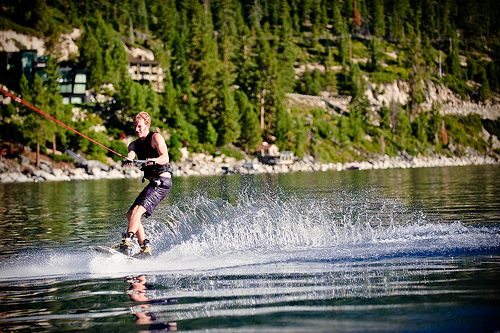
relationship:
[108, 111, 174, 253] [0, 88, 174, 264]
man enjoying skiing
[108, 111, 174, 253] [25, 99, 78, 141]
man being pulled rope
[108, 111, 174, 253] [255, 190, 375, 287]
man moving through water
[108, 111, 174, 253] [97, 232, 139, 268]
man on ski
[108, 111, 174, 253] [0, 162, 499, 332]
man water skiing on body/water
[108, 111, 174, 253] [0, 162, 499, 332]
man skiing on body/water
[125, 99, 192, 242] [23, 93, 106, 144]
man holding line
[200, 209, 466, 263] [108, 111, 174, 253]
wake behind a man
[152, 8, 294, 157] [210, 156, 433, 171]
trees along shore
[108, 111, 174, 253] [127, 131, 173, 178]
man wearing a clothes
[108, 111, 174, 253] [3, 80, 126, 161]
man holding onto rope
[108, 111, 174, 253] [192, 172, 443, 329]
man skiing on water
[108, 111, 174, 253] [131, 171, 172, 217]
man wearing swim trunks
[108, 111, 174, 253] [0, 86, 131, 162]
man holding onto a rope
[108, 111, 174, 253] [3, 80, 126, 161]
man holding rope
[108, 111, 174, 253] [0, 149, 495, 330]
man in water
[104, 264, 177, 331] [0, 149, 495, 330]
reflection in water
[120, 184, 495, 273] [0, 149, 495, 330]
splashes of water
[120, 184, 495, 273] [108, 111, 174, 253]
splashes behind man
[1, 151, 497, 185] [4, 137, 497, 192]
stones on shore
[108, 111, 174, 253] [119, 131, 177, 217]
man wearing clothes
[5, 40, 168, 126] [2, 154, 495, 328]
buildings on river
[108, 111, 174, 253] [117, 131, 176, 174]
man wears top